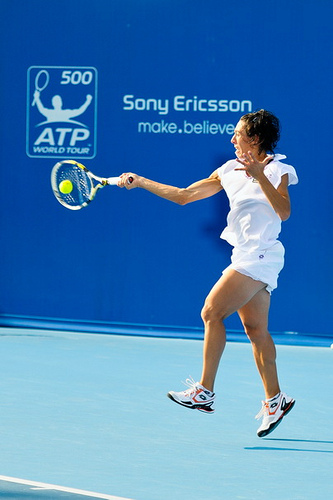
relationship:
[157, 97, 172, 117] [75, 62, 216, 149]
letter on board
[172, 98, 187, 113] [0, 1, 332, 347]
letter on board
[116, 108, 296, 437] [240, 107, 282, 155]
lady has hair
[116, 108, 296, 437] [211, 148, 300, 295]
lady wears clothes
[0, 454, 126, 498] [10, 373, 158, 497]
line on tennis court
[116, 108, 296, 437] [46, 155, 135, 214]
lady holds racket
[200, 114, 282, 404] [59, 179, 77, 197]
lady hitting ball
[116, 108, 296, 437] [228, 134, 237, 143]
lady has nose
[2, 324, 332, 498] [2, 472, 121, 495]
tennis court has part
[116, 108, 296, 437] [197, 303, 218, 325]
lady has knee